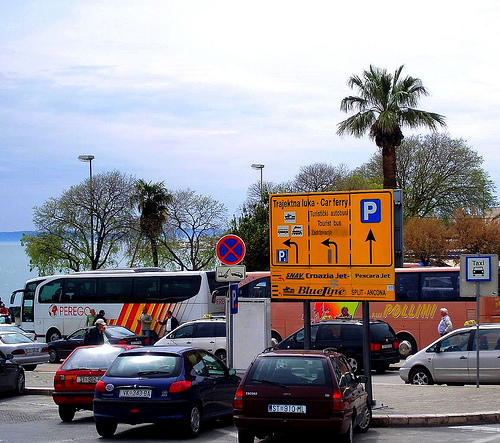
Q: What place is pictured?
A: It is a parking lot.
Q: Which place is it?
A: It is a parking lot.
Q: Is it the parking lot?
A: Yes, it is the parking lot.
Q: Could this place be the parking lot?
A: Yes, it is the parking lot.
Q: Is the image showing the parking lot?
A: Yes, it is showing the parking lot.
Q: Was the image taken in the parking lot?
A: Yes, it was taken in the parking lot.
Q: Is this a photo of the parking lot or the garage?
A: It is showing the parking lot.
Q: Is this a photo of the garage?
A: No, the picture is showing the parking lot.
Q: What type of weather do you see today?
A: It is cloudy.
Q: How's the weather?
A: It is cloudy.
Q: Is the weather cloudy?
A: Yes, it is cloudy.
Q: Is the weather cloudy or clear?
A: It is cloudy.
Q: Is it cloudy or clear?
A: It is cloudy.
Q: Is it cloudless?
A: No, it is cloudy.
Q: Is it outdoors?
A: Yes, it is outdoors.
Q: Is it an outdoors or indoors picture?
A: It is outdoors.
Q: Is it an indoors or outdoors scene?
A: It is outdoors.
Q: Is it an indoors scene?
A: No, it is outdoors.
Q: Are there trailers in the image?
A: No, there are no trailers.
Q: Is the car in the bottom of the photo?
A: Yes, the car is in the bottom of the image.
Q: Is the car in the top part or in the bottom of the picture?
A: The car is in the bottom of the image.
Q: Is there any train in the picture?
A: No, there are no trains.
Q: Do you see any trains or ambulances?
A: No, there are no trains or ambulances.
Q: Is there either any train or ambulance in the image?
A: No, there are no trains or ambulances.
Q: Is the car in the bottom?
A: Yes, the car is in the bottom of the image.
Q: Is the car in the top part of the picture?
A: No, the car is in the bottom of the image.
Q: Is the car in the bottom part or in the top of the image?
A: The car is in the bottom of the image.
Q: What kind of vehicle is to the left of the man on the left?
A: The vehicle is a car.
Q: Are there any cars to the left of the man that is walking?
A: Yes, there is a car to the left of the man.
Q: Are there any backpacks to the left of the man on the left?
A: No, there is a car to the left of the man.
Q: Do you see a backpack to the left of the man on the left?
A: No, there is a car to the left of the man.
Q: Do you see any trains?
A: No, there are no trains.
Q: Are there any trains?
A: No, there are no trains.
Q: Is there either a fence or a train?
A: No, there are no trains or fences.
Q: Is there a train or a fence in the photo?
A: No, there are no trains or fences.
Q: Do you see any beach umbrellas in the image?
A: No, there are no beach umbrellas.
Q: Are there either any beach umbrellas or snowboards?
A: No, there are no beach umbrellas or snowboards.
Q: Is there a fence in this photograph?
A: No, there are no fences.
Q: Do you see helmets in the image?
A: No, there are no helmets.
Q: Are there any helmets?
A: No, there are no helmets.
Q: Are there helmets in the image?
A: No, there are no helmets.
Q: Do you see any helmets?
A: No, there are no helmets.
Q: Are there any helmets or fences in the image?
A: No, there are no helmets or fences.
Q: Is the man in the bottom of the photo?
A: Yes, the man is in the bottom of the image.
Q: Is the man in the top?
A: No, the man is in the bottom of the image.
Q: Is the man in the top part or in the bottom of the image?
A: The man is in the bottom of the image.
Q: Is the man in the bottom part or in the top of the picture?
A: The man is in the bottom of the image.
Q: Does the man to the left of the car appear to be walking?
A: Yes, the man is walking.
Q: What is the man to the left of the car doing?
A: The man is walking.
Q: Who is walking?
A: The man is walking.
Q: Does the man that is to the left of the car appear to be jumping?
A: No, the man is walking.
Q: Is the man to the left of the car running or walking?
A: The man is walking.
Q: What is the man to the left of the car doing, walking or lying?
A: The man is walking.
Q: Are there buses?
A: Yes, there is a bus.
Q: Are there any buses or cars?
A: Yes, there is a bus.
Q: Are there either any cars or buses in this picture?
A: Yes, there is a bus.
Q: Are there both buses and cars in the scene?
A: Yes, there are both a bus and a car.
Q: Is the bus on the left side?
A: Yes, the bus is on the left of the image.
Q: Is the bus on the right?
A: No, the bus is on the left of the image.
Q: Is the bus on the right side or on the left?
A: The bus is on the left of the image.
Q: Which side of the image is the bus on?
A: The bus is on the left of the image.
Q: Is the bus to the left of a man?
A: Yes, the bus is to the left of a man.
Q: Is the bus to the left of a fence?
A: No, the bus is to the left of a man.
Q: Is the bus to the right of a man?
A: No, the bus is to the left of a man.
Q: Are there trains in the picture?
A: No, there are no trains.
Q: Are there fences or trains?
A: No, there are no trains or fences.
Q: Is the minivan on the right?
A: Yes, the minivan is on the right of the image.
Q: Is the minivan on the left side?
A: No, the minivan is on the right of the image.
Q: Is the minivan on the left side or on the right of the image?
A: The minivan is on the right of the image.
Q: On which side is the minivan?
A: The minivan is on the right of the image.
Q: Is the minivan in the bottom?
A: Yes, the minivan is in the bottom of the image.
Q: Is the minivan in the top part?
A: No, the minivan is in the bottom of the image.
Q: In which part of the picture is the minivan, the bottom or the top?
A: The minivan is in the bottom of the image.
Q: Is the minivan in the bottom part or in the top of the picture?
A: The minivan is in the bottom of the image.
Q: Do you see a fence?
A: No, there are no fences.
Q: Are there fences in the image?
A: No, there are no fences.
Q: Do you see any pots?
A: No, there are no pots.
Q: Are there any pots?
A: No, there are no pots.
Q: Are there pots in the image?
A: No, there are no pots.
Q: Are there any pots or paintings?
A: No, there are no pots or paintings.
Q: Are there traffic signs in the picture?
A: Yes, there is a traffic sign.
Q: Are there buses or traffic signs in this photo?
A: Yes, there is a traffic sign.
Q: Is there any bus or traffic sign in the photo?
A: Yes, there is a traffic sign.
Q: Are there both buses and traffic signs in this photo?
A: Yes, there are both a traffic sign and a bus.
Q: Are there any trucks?
A: No, there are no trucks.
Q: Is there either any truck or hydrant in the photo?
A: No, there are no trucks or fire hydrants.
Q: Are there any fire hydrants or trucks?
A: No, there are no trucks or fire hydrants.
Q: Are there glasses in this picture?
A: No, there are no glasses.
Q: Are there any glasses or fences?
A: No, there are no glasses or fences.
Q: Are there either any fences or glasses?
A: No, there are no glasses or fences.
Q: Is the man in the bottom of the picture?
A: Yes, the man is in the bottom of the image.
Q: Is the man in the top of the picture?
A: No, the man is in the bottom of the image.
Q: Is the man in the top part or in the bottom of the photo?
A: The man is in the bottom of the image.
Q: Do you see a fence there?
A: No, there are no fences.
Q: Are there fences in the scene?
A: No, there are no fences.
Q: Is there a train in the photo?
A: No, there are no trains.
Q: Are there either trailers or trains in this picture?
A: No, there are no trains or trailers.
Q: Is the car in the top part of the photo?
A: No, the car is in the bottom of the image.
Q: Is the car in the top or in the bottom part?
A: The car is in the bottom of the image.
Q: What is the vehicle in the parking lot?
A: The vehicle is a car.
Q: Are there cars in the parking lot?
A: Yes, there is a car in the parking lot.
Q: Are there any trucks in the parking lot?
A: No, there is a car in the parking lot.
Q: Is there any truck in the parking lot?
A: No, there is a car in the parking lot.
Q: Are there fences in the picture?
A: No, there are no fences.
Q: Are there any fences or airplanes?
A: No, there are no fences or airplanes.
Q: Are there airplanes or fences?
A: No, there are no fences or airplanes.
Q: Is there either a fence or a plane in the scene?
A: No, there are no fences or airplanes.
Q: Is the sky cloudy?
A: Yes, the sky is cloudy.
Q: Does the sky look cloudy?
A: Yes, the sky is cloudy.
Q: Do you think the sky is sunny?
A: No, the sky is cloudy.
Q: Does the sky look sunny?
A: No, the sky is cloudy.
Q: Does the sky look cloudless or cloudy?
A: The sky is cloudy.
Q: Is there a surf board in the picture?
A: No, there are no surfboards.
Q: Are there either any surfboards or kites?
A: No, there are no surfboards or kites.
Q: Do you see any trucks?
A: No, there are no trucks.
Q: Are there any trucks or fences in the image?
A: No, there are no trucks or fences.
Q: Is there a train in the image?
A: No, there are no trains.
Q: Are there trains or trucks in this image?
A: No, there are no trains or trucks.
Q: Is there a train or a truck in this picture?
A: No, there are no trains or trucks.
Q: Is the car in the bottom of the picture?
A: Yes, the car is in the bottom of the image.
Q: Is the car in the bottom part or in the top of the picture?
A: The car is in the bottom of the image.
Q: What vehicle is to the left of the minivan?
A: The vehicle is a car.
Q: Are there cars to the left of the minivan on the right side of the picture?
A: Yes, there is a car to the left of the minivan.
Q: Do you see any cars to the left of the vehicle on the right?
A: Yes, there is a car to the left of the minivan.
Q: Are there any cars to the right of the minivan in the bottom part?
A: No, the car is to the left of the minivan.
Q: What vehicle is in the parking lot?
A: The vehicle is a car.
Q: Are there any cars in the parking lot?
A: Yes, there is a car in the parking lot.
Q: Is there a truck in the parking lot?
A: No, there is a car in the parking lot.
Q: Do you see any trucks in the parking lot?
A: No, there is a car in the parking lot.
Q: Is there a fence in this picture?
A: No, there are no fences.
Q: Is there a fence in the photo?
A: No, there are no fences.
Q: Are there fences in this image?
A: No, there are no fences.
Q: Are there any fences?
A: No, there are no fences.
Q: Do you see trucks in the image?
A: No, there are no trucks.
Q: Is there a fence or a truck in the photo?
A: No, there are no trucks or fences.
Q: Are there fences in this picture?
A: No, there are no fences.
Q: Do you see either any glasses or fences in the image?
A: No, there are no fences or glasses.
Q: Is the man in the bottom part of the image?
A: Yes, the man is in the bottom of the image.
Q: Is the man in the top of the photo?
A: No, the man is in the bottom of the image.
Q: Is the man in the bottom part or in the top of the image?
A: The man is in the bottom of the image.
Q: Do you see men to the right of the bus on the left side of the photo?
A: Yes, there is a man to the right of the bus.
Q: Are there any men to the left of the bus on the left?
A: No, the man is to the right of the bus.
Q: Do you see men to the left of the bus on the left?
A: No, the man is to the right of the bus.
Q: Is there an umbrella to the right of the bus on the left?
A: No, there is a man to the right of the bus.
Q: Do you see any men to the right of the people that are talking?
A: Yes, there is a man to the right of the people.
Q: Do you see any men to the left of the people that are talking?
A: No, the man is to the right of the people.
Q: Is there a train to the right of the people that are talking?
A: No, there is a man to the right of the people.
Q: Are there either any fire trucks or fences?
A: No, there are no fences or fire trucks.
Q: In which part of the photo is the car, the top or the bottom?
A: The car is in the bottom of the image.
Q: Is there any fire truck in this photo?
A: No, there are no fire trucks.